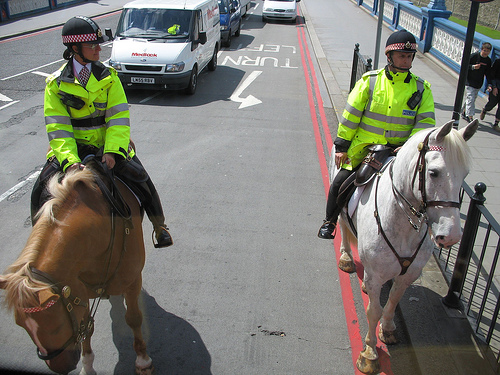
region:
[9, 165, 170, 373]
a light brown horse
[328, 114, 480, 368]
a white standing horse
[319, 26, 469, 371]
a police officer riding a horse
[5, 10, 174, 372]
a police officer riding a horse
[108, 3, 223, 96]
a white van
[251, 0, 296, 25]
a small white car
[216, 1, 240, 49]
a small blue car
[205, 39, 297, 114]
painted traffic directions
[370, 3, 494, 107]
a blue and white wall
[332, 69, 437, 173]
a yellow safety coat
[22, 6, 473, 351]
two police officers on horseback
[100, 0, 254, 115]
a white van with red writing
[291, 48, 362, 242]
red stripes on pavement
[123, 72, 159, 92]
a european license plate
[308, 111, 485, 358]
a white horse with alert ears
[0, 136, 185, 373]
a brown horse with white ankles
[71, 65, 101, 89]
a checkered tie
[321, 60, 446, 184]
a bright yellow jacket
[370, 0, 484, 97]
a blue and white fence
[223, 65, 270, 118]
a white arrow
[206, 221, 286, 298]
The ground is gray.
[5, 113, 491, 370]
Two horses are in the picture.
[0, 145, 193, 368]
This horse is brown.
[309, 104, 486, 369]
This horse is white.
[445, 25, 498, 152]
People are walking on the sidewalk.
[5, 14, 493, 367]
People are riding the horses.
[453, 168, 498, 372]
A guardrail is in the picture.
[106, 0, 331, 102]
Cars are on the road.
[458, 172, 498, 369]
The guardrail is black.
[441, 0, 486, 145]
A light pole.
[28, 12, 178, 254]
Person wearing eye glasses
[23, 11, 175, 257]
Person riding brown horse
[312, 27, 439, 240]
Person riding white horse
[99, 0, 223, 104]
Van is white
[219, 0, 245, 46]
Blue car behind white van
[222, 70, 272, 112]
White arrow on road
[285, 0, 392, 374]
Red traffic line on road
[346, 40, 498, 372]
Black metal gate next to white horse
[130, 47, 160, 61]
Red logo on white van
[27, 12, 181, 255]
Person wearing helmet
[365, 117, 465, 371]
the horse is white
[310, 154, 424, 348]
the horse is white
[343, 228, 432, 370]
the horse is white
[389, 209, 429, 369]
the horse is white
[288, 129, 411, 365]
the horse is white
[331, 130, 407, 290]
the horse is white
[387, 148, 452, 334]
the horse is white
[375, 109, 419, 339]
the horse is white